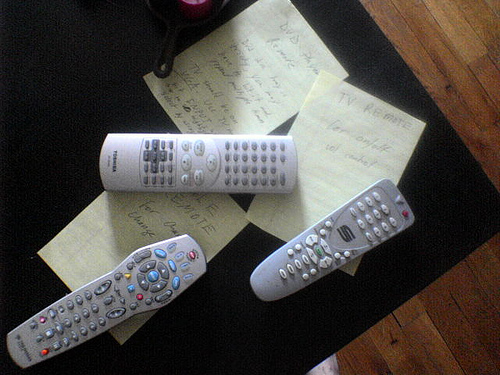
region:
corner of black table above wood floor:
[0, 0, 498, 373]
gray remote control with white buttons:
[250, 179, 415, 302]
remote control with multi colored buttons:
[7, 236, 206, 368]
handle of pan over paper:
[148, 0, 228, 79]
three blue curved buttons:
[155, 249, 180, 290]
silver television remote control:
[96, 132, 300, 197]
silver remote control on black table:
[247, 170, 415, 301]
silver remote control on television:
[5, 233, 207, 369]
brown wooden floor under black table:
[6, 8, 498, 373]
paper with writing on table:
[38, 150, 250, 330]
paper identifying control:
[248, 60, 425, 275]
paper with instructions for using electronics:
[143, 0, 350, 157]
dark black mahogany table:
[5, 3, 499, 368]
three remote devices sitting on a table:
[3, 123, 424, 365]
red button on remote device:
[184, 241, 204, 264]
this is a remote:
[247, 174, 419, 301]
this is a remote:
[5, 210, 208, 373]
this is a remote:
[96, 130, 298, 197]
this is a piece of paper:
[246, 65, 428, 276]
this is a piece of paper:
[29, 150, 249, 347]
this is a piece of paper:
[138, 0, 352, 157]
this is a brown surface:
[385, 320, 490, 370]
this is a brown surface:
[392, 5, 492, 56]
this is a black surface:
[9, 10, 106, 128]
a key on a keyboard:
[386, 215, 401, 225]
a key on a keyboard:
[361, 217, 369, 236]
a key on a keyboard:
[160, 266, 171, 276]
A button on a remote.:
[147, 268, 159, 282]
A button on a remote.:
[124, 282, 136, 292]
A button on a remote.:
[126, 274, 133, 280]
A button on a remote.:
[92, 303, 99, 312]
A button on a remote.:
[98, 317, 105, 327]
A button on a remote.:
[82, 308, 89, 317]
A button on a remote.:
[74, 295, 84, 305]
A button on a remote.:
[64, 318, 71, 326]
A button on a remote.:
[207, 154, 216, 171]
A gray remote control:
[93, 125, 303, 202]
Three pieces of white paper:
[30, 0, 427, 347]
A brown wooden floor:
[330, 0, 495, 370]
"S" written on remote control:
[330, 215, 362, 250]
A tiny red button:
[392, 200, 412, 221]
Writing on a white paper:
[290, 67, 425, 177]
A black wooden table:
[0, 0, 495, 370]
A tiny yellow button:
[115, 265, 135, 286]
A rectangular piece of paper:
[240, 61, 432, 279]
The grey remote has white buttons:
[233, 186, 437, 303]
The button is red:
[398, 205, 413, 223]